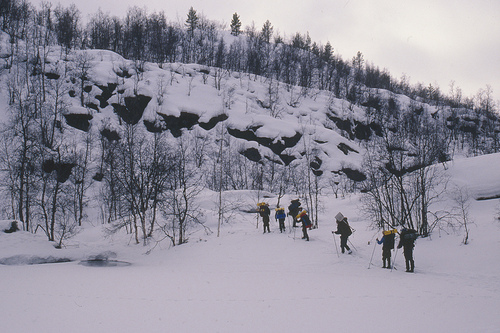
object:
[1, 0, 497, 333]
place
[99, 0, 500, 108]
sky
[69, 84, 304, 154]
rocks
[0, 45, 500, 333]
snow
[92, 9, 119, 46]
trees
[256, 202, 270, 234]
people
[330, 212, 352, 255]
person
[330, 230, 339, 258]
stick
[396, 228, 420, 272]
man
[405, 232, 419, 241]
bag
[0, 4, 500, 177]
mountain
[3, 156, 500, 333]
ground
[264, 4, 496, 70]
clouds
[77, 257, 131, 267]
water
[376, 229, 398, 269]
skier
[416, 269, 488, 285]
marks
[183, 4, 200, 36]
tree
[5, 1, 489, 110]
evergreens